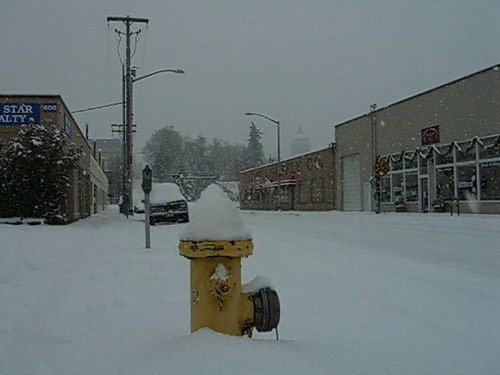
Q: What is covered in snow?
A: Ground.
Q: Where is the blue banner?
A: On building.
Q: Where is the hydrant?
A: Sidewalk.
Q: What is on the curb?
A: The yellow fire hydrant.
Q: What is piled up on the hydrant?
A: Snow.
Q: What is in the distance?
A: The trees.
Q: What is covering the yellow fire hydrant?
A: The snow.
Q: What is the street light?
A: Tall.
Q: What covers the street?
A: Snow.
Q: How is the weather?
A: Snowy.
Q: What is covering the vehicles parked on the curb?
A: Snow.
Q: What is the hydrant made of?
A: Metal.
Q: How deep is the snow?
A: A few inches.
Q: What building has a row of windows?
A: The tan one on the right.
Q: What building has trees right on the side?
A: The brick building on the left.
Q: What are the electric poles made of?
A: Wood.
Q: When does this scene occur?
A: Daytime.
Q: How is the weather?
A: It is snowing.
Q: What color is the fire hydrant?
A: Yellow.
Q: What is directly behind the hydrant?
A: A parking meter.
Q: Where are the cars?
A: Parked on the left side of the street.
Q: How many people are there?
A: None.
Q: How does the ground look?
A: Covered in snow.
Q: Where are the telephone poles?
A: On the left side of street.